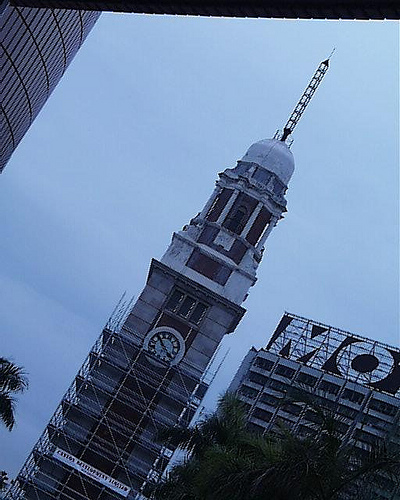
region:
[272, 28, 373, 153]
the tip of the building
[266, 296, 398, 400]
the letters MO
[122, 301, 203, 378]
an old clock on the tower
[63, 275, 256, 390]
part of the tall tower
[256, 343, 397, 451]
windows on the building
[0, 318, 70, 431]
part of a palm tree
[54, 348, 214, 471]
stair way up the tower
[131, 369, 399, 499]
a big tree in the bottom right corner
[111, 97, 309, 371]
half of a tall tower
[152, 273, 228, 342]
windows above the clock on the tower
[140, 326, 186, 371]
Large, round-faced clock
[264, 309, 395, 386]
Two large, white letters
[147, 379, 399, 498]
Tree with thin pointed leaves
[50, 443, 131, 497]
Thin, long white banner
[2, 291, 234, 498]
Metal scaffolding on a building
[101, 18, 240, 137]
Blue color of the sky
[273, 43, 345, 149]
Metal framed spire with a long sharp tip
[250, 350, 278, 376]
Top floor corner window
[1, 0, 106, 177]
Round building with dark ringed sections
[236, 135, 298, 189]
Large grey dome shape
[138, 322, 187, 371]
A clock on a tower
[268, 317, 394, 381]
The letters "MO" on a billboard atop a building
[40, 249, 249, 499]
A clocktower with scaffolding attached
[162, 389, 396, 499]
green trees in front of buildings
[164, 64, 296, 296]
the spire of a tower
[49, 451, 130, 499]
a white banner with lettering on the clocktower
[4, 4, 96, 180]
a partial view of a skyscraper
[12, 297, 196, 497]
scaffolding on a building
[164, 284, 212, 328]
windows above a clock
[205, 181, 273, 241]
pillars at the top of the clocktower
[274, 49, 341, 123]
tall metal spire of tower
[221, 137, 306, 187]
large white dome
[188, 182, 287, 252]
group of white columns on tower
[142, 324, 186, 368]
large white clock on tower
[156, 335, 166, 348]
long hand on clock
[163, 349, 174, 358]
short hand on clock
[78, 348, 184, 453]
scaffolding around tower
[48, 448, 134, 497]
white and red banner on scaffolding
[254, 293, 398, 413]
white and black sign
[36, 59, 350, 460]
large clock tower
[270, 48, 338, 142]
long metal tip of tower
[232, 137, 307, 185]
white dome on tower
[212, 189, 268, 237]
white pillars on tower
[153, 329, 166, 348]
long hand of clock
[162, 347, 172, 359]
short hand of clock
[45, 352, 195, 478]
scaffolding on the side of building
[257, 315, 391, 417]
scaffolding next to sign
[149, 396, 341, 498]
palm fronds in foreground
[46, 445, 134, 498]
white banner on scaffolding